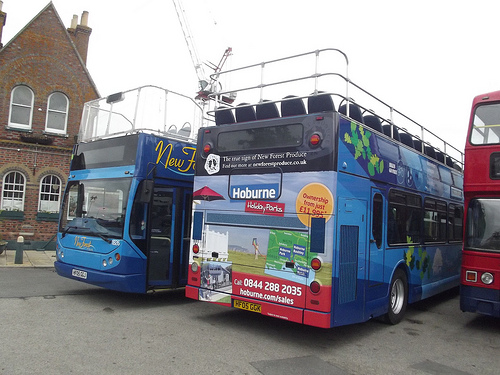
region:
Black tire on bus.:
[386, 271, 420, 340]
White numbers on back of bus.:
[238, 276, 294, 303]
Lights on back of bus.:
[185, 245, 337, 307]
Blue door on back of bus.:
[361, 196, 386, 286]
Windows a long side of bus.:
[393, 200, 447, 236]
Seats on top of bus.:
[253, 85, 325, 116]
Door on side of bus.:
[157, 194, 185, 296]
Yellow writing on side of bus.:
[151, 143, 193, 183]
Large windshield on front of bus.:
[60, 189, 130, 240]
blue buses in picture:
[23, 12, 494, 354]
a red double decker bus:
[408, 79, 498, 324]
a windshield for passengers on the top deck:
[64, 95, 207, 147]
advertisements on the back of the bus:
[187, 121, 334, 327]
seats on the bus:
[206, 74, 461, 176]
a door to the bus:
[143, 182, 193, 289]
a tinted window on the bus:
[351, 162, 464, 259]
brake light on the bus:
[186, 112, 339, 174]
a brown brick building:
[4, 52, 76, 263]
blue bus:
[195, 58, 426, 340]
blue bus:
[61, 81, 182, 290]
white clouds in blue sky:
[442, 17, 495, 51]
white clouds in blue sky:
[366, 21, 392, 38]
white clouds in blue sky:
[248, 48, 300, 72]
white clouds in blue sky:
[165, 38, 212, 56]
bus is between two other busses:
[182, 43, 463, 334]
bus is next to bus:
[50, 82, 189, 304]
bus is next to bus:
[460, 90, 499, 326]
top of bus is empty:
[202, 47, 464, 169]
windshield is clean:
[60, 172, 132, 237]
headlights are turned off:
[53, 248, 116, 268]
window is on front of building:
[7, 83, 34, 130]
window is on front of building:
[40, 87, 71, 134]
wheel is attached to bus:
[384, 260, 409, 321]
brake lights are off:
[202, 129, 321, 155]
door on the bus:
[151, 171, 184, 286]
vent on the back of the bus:
[337, 212, 362, 312]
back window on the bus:
[208, 125, 303, 147]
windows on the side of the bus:
[391, 185, 456, 247]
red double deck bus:
[456, 76, 498, 310]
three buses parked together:
[59, 45, 499, 330]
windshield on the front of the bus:
[62, 179, 121, 228]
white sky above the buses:
[251, 10, 371, 38]